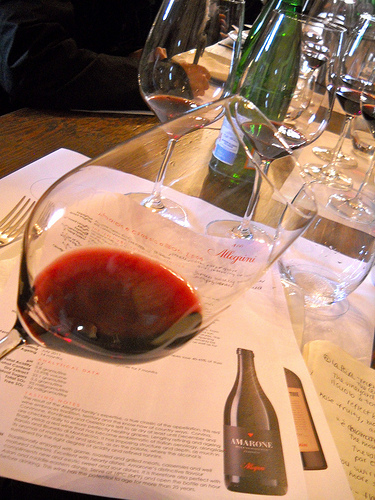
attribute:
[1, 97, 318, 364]
glass — wine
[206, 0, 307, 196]
bottle — green, glass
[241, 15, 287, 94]
bottle — wine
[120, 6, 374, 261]
glasses — wine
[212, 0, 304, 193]
bottle — green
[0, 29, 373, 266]
table — wooden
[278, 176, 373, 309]
glass cup — small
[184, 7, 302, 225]
bottle — green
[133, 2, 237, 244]
glasses — wine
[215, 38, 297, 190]
bottle — green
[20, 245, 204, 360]
wine — red